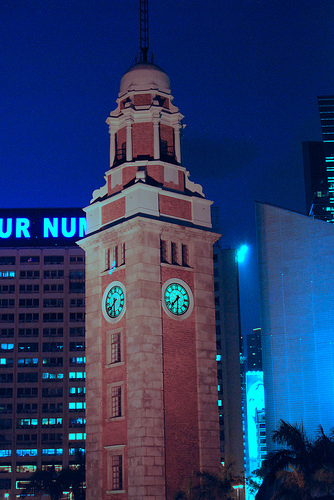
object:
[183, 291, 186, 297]
numbers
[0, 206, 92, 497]
building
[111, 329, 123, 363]
window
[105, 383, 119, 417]
window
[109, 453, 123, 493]
window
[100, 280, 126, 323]
clock face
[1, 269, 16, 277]
light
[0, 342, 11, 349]
light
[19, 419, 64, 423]
light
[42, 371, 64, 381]
light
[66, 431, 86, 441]
light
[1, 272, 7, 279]
windows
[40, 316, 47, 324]
windows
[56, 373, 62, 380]
windows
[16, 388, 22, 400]
windows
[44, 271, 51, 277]
windows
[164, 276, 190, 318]
clock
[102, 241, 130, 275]
three windows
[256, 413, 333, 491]
tree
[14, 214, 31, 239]
lights on top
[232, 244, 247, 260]
street light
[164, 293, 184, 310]
hand on clock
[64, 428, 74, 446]
windows under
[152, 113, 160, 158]
stone columns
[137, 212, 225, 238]
ledge above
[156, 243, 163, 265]
small windows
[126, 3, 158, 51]
lightning rod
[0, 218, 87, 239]
lit sign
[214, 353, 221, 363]
light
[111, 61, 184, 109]
dome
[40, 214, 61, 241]
illuminated letters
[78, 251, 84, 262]
windows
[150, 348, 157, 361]
red bricks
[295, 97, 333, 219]
lit building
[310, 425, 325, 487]
palm trees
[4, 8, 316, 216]
sky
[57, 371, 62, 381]
lights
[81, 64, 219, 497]
building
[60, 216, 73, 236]
words